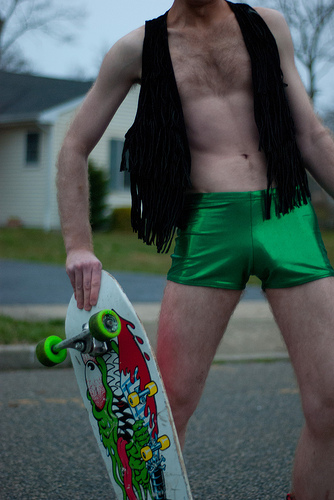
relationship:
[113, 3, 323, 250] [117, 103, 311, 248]
vest with fringe